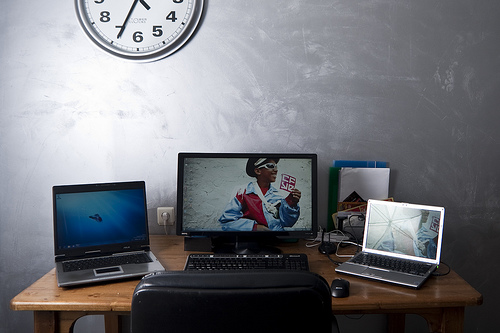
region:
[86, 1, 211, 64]
clock on the wall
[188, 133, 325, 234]
computer monitor is on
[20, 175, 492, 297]
two laptops on the table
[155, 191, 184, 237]
power cord in the outlet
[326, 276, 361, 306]
computer mouse is black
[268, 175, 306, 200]
man is holding a red and white sign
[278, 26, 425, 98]
wall is silver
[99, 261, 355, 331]
computer chair is black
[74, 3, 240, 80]
clock frame is silver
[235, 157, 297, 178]
man is wearing sunglasses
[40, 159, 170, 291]
small silver and black laptop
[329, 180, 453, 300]
very small silver laptop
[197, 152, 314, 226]
man holding card in glasses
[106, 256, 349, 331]
black leather computer chair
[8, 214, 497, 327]
small wooden computer desk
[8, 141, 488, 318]
laptops sitting on a table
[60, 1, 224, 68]
large metal clock on wall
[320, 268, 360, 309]
small black computer mouse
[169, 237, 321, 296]
small black computer keyboard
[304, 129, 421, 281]
papers in basket behind computer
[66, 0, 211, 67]
clock on wall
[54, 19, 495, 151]
white wall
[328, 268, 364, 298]
mouse for computer on table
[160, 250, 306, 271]
keyboard to computer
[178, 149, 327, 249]
computer screen on table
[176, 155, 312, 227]
man holding up a red card inside monitor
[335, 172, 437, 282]
lap top computer on desk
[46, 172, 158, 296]
a small laptop with a snowboarder on screen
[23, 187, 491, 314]
a brown computer desk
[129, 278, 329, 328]
black chair on floor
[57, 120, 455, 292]
Three computers on the desk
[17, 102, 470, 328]
Computer desk and chair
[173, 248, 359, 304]
Keyboard and mouse of the desktop computer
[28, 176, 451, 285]
Two silver laptops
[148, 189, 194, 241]
Electric socket in the wall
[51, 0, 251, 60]
Big silver clock on the wall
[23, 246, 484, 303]
Wooden desk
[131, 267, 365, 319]
Black leather chair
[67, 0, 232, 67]
4.35 PM time in the clock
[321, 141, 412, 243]
Papers on the desk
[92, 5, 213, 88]
Clock hanging on the wall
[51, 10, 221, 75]
Clock reads 4:35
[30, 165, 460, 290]
Two laptops and a desktop on a desk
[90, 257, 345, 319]
A black leather office chair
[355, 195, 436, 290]
A silver laptop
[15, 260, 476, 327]
A wooden desk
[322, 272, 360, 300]
A black mouse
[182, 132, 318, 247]
The destop screen shows a man wearing sunglasses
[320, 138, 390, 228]
File folders and papers in a divider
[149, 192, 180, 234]
A single white outlet